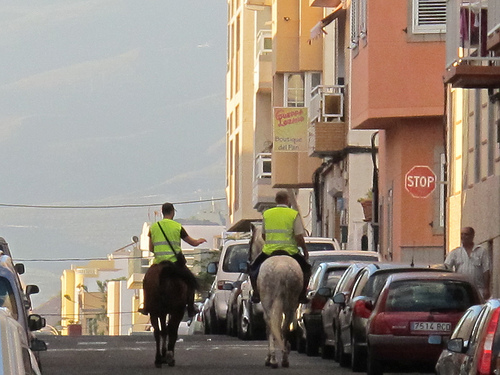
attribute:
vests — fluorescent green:
[144, 205, 302, 263]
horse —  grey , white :
[216, 246, 328, 360]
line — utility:
[0, 190, 225, 219]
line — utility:
[13, 243, 200, 264]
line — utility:
[34, 306, 141, 318]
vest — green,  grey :
[249, 203, 309, 269]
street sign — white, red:
[403, 162, 438, 198]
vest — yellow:
[147, 219, 184, 264]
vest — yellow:
[260, 206, 300, 258]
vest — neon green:
[262, 206, 299, 254]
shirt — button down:
[437, 240, 496, 300]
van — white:
[175, 204, 291, 354]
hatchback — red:
[360, 265, 487, 354]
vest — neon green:
[124, 184, 216, 265]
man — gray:
[233, 186, 312, 271]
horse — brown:
[135, 259, 202, 368]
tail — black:
[159, 256, 204, 290]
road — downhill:
[11, 316, 363, 372]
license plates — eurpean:
[408, 319, 455, 331]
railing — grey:
[443, 4, 498, 64]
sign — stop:
[400, 166, 440, 197]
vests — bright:
[139, 212, 307, 256]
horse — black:
[141, 257, 203, 365]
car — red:
[359, 252, 477, 353]